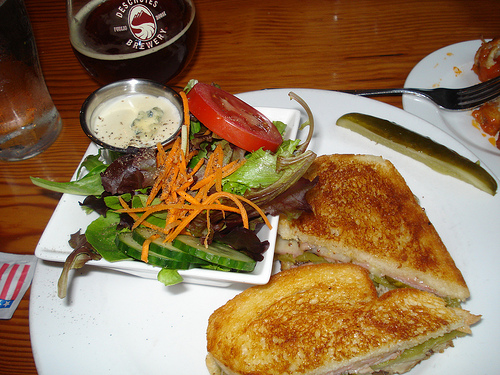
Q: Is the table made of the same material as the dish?
A: No, the table is made of wood and the dish is made of metal.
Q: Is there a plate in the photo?
A: Yes, there is a plate.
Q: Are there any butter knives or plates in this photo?
A: Yes, there is a plate.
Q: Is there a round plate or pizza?
A: Yes, there is a round plate.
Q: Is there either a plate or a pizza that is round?
A: Yes, the plate is round.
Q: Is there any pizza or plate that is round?
A: Yes, the plate is round.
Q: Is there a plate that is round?
A: Yes, there is a round plate.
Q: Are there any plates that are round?
A: Yes, there is a plate that is round.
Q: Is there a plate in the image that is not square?
A: Yes, there is a round plate.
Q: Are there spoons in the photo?
A: No, there are no spoons.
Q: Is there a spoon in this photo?
A: No, there are no spoons.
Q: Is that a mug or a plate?
A: That is a plate.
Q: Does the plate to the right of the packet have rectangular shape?
A: No, the plate is round.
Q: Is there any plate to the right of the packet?
A: Yes, there is a plate to the right of the packet.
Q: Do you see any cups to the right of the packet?
A: No, there is a plate to the right of the packet.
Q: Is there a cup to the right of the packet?
A: No, there is a plate to the right of the packet.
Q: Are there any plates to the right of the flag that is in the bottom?
A: Yes, there is a plate to the right of the flag.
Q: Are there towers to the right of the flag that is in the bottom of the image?
A: No, there is a plate to the right of the flag.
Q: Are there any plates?
A: Yes, there is a plate.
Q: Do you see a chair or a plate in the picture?
A: Yes, there is a plate.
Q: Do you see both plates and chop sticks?
A: No, there is a plate but no chopsticks.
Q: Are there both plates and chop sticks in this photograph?
A: No, there is a plate but no chopsticks.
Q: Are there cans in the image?
A: No, there are no cans.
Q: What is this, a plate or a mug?
A: This is a plate.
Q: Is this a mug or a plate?
A: This is a plate.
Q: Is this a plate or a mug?
A: This is a plate.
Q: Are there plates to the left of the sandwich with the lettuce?
A: Yes, there is a plate to the left of the sandwich.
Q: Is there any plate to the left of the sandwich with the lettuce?
A: Yes, there is a plate to the left of the sandwich.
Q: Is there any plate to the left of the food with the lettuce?
A: Yes, there is a plate to the left of the sandwich.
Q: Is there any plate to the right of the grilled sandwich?
A: No, the plate is to the left of the sandwich.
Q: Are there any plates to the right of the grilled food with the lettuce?
A: No, the plate is to the left of the sandwich.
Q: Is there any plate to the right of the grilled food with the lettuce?
A: No, the plate is to the left of the sandwich.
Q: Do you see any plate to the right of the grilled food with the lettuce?
A: No, the plate is to the left of the sandwich.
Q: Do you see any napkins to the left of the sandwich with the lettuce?
A: No, there is a plate to the left of the sandwich.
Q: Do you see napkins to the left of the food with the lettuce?
A: No, there is a plate to the left of the sandwich.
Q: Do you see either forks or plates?
A: Yes, there is a plate.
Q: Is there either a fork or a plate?
A: Yes, there is a plate.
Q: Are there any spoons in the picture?
A: No, there are no spoons.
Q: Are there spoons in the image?
A: No, there are no spoons.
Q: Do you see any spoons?
A: No, there are no spoons.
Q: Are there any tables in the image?
A: Yes, there is a table.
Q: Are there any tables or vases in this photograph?
A: Yes, there is a table.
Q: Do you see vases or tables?
A: Yes, there is a table.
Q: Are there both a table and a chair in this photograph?
A: No, there is a table but no chairs.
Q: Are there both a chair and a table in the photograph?
A: No, there is a table but no chairs.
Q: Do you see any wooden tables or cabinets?
A: Yes, there is a wood table.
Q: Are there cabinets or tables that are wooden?
A: Yes, the table is wooden.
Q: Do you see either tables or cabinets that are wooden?
A: Yes, the table is wooden.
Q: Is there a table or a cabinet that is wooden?
A: Yes, the table is wooden.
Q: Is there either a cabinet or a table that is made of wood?
A: Yes, the table is made of wood.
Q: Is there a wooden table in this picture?
A: Yes, there is a wood table.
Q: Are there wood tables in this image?
A: Yes, there is a wood table.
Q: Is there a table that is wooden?
A: Yes, there is a table that is wooden.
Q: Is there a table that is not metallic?
A: Yes, there is a wooden table.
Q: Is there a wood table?
A: Yes, there is a table that is made of wood.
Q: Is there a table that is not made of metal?
A: Yes, there is a table that is made of wood.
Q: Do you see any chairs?
A: No, there are no chairs.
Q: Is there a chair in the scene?
A: No, there are no chairs.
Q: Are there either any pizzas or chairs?
A: No, there are no chairs or pizzas.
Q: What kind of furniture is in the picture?
A: The furniture is a table.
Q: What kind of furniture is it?
A: The piece of furniture is a table.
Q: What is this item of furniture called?
A: This is a table.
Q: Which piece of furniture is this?
A: This is a table.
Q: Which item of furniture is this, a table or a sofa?
A: This is a table.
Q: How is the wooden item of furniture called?
A: The piece of furniture is a table.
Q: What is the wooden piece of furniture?
A: The piece of furniture is a table.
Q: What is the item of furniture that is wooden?
A: The piece of furniture is a table.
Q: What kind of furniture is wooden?
A: The furniture is a table.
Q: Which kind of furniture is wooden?
A: The furniture is a table.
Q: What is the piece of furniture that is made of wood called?
A: The piece of furniture is a table.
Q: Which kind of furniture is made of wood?
A: The furniture is a table.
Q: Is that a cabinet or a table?
A: That is a table.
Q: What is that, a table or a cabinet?
A: That is a table.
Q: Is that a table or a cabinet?
A: That is a table.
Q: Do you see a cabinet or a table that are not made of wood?
A: No, there is a table but it is made of wood.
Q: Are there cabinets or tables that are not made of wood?
A: No, there is a table but it is made of wood.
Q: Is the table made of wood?
A: Yes, the table is made of wood.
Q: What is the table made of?
A: The table is made of wood.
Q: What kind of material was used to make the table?
A: The table is made of wood.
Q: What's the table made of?
A: The table is made of wood.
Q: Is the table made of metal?
A: No, the table is made of wood.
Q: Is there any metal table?
A: No, there is a table but it is made of wood.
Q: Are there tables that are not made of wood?
A: No, there is a table but it is made of wood.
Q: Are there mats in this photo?
A: No, there are no mats.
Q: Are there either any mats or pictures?
A: No, there are no mats or pictures.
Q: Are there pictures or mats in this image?
A: No, there are no mats or pictures.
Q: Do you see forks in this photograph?
A: Yes, there is a fork.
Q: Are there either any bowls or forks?
A: Yes, there is a fork.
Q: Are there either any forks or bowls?
A: Yes, there is a fork.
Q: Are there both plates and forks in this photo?
A: Yes, there are both a fork and a plate.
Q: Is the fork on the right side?
A: Yes, the fork is on the right of the image.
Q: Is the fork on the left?
A: No, the fork is on the right of the image.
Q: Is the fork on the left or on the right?
A: The fork is on the right of the image.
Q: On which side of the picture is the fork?
A: The fork is on the right of the image.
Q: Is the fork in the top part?
A: Yes, the fork is in the top of the image.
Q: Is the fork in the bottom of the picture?
A: No, the fork is in the top of the image.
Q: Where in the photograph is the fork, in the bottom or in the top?
A: The fork is in the top of the image.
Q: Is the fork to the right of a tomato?
A: Yes, the fork is to the right of a tomato.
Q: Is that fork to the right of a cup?
A: No, the fork is to the right of a tomato.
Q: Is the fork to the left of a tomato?
A: No, the fork is to the right of a tomato.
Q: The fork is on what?
A: The fork is on the plate.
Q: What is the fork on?
A: The fork is on the plate.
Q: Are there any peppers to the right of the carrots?
A: No, there is a fork to the right of the carrots.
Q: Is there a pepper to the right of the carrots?
A: No, there is a fork to the right of the carrots.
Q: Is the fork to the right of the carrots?
A: Yes, the fork is to the right of the carrots.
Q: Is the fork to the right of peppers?
A: No, the fork is to the right of the carrots.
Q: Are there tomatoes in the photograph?
A: Yes, there is a tomato.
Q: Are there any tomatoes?
A: Yes, there is a tomato.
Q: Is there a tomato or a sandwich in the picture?
A: Yes, there is a tomato.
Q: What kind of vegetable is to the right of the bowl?
A: The vegetable is a tomato.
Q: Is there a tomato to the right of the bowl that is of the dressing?
A: Yes, there is a tomato to the right of the bowl.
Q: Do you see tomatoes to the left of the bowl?
A: No, the tomato is to the right of the bowl.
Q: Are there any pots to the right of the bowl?
A: No, there is a tomato to the right of the bowl.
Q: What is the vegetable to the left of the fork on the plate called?
A: The vegetable is a tomato.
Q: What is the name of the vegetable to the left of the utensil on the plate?
A: The vegetable is a tomato.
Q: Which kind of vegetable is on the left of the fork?
A: The vegetable is a tomato.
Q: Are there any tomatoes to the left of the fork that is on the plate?
A: Yes, there is a tomato to the left of the fork.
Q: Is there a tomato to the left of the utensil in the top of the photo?
A: Yes, there is a tomato to the left of the fork.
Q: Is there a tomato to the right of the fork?
A: No, the tomato is to the left of the fork.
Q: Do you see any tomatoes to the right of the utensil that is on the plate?
A: No, the tomato is to the left of the fork.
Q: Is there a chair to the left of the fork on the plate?
A: No, there is a tomato to the left of the fork.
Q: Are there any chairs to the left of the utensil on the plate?
A: No, there is a tomato to the left of the fork.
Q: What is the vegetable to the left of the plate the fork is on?
A: The vegetable is a tomato.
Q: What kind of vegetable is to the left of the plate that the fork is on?
A: The vegetable is a tomato.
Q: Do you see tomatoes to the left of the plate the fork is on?
A: Yes, there is a tomato to the left of the plate.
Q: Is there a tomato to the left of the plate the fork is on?
A: Yes, there is a tomato to the left of the plate.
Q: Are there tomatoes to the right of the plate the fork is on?
A: No, the tomato is to the left of the plate.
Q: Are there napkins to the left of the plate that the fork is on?
A: No, there is a tomato to the left of the plate.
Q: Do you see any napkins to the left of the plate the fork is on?
A: No, there is a tomato to the left of the plate.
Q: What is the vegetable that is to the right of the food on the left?
A: The vegetable is a tomato.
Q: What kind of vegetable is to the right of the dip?
A: The vegetable is a tomato.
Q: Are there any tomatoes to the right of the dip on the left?
A: Yes, there is a tomato to the right of the dip.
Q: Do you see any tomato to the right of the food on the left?
A: Yes, there is a tomato to the right of the dip.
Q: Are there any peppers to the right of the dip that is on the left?
A: No, there is a tomato to the right of the dip.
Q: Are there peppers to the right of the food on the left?
A: No, there is a tomato to the right of the dip.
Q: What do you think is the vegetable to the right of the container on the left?
A: The vegetable is a tomato.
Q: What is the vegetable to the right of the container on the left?
A: The vegetable is a tomato.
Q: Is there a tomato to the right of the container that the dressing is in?
A: Yes, there is a tomato to the right of the container.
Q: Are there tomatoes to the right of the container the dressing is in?
A: Yes, there is a tomato to the right of the container.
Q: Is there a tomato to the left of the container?
A: No, the tomato is to the right of the container.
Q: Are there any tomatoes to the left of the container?
A: No, the tomato is to the right of the container.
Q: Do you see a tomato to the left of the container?
A: No, the tomato is to the right of the container.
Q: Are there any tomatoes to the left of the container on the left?
A: No, the tomato is to the right of the container.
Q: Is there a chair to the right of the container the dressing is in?
A: No, there is a tomato to the right of the container.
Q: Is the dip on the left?
A: Yes, the dip is on the left of the image.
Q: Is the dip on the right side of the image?
A: No, the dip is on the left of the image.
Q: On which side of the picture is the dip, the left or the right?
A: The dip is on the left of the image.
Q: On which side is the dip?
A: The dip is on the left of the image.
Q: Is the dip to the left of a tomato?
A: Yes, the dip is to the left of a tomato.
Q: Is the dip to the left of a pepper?
A: No, the dip is to the left of a tomato.